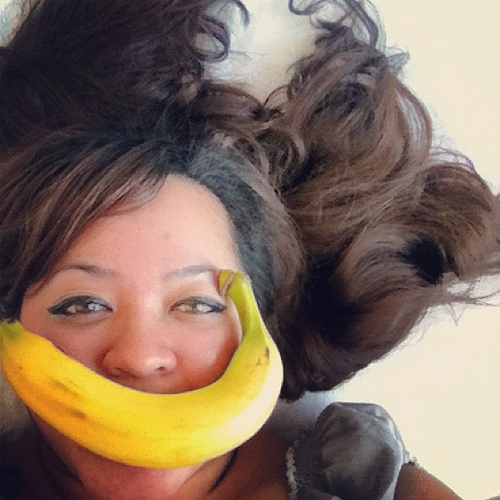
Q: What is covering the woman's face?
A: Banana.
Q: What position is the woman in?
A: Lying down.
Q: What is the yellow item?
A: Banana.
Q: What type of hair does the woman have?
A: Long brown hair.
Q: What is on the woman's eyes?
A: Makeup.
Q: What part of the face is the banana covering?
A: Lips.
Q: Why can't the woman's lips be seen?
A: They are covered by a banana.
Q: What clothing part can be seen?
A: Sleeve of loouse.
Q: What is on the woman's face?
A: A banana.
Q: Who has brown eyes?
A: The woman.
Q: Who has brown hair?
A: The woman.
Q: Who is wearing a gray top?
A: The woman.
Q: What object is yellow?
A: The banana.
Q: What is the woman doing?
A: Laying down.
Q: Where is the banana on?
A: Her mouth.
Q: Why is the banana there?
A: For a smile.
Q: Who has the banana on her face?
A: A woman.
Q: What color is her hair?
A: Brown.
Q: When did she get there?
A: Moments ago.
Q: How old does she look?
A: In 30's.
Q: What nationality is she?
A: Latin.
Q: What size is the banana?
A: Large.